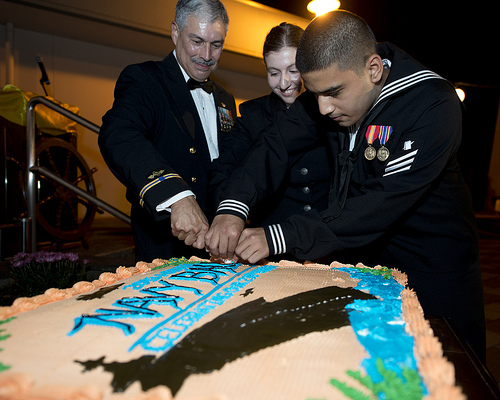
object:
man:
[100, 0, 238, 267]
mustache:
[187, 55, 216, 67]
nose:
[199, 42, 215, 60]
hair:
[170, 0, 232, 33]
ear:
[169, 19, 177, 42]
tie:
[186, 79, 213, 93]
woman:
[235, 18, 339, 262]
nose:
[279, 76, 289, 90]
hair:
[264, 22, 305, 55]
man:
[207, 5, 491, 369]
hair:
[292, 10, 371, 76]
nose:
[318, 97, 333, 115]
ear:
[369, 55, 383, 83]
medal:
[363, 123, 378, 160]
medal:
[377, 123, 392, 161]